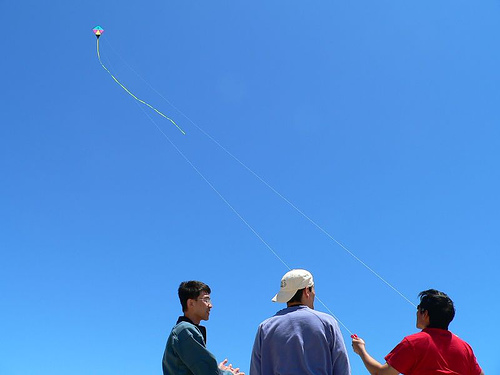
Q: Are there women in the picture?
A: No, there are no women.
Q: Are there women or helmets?
A: No, there are no women or helmets.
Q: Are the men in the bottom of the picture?
A: Yes, the men are in the bottom of the image.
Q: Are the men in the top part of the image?
A: No, the men are in the bottom of the image.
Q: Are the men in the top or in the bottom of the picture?
A: The men are in the bottom of the image.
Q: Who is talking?
A: The men are talking.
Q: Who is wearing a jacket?
A: The men are wearing a jacket.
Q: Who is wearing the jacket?
A: The men are wearing a jacket.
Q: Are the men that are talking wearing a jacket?
A: Yes, the men are wearing a jacket.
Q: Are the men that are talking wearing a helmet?
A: No, the men are wearing a jacket.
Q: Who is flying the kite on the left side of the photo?
A: The men are flying the kite.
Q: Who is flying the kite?
A: The men are flying the kite.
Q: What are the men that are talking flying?
A: The men are flying the kite.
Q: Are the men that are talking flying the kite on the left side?
A: Yes, the men are flying the kite.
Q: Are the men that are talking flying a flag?
A: No, the men are flying the kite.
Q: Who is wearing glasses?
A: The men are wearing glasses.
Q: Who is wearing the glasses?
A: The men are wearing glasses.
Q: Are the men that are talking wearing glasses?
A: Yes, the men are wearing glasses.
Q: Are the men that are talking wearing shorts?
A: No, the men are wearing glasses.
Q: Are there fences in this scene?
A: No, there are no fences.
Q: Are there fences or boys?
A: No, there are no fences or boys.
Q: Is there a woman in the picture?
A: No, there are no women.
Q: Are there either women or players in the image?
A: No, there are no women or players.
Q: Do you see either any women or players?
A: No, there are no women or players.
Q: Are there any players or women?
A: No, there are no women or players.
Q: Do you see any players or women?
A: No, there are no women or players.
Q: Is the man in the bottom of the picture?
A: Yes, the man is in the bottom of the image.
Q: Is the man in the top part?
A: No, the man is in the bottom of the image.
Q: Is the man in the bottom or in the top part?
A: The man is in the bottom of the image.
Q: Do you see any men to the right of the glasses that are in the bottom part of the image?
A: Yes, there is a man to the right of the glasses.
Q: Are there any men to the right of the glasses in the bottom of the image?
A: Yes, there is a man to the right of the glasses.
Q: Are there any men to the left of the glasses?
A: No, the man is to the right of the glasses.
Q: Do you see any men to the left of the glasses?
A: No, the man is to the right of the glasses.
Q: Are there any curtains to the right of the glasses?
A: No, there is a man to the right of the glasses.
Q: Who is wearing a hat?
A: The man is wearing a hat.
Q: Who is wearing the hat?
A: The man is wearing a hat.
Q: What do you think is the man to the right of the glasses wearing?
A: The man is wearing a hat.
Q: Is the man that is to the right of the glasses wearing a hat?
A: Yes, the man is wearing a hat.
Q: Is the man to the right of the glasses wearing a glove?
A: No, the man is wearing a hat.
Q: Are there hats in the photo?
A: Yes, there is a hat.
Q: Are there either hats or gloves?
A: Yes, there is a hat.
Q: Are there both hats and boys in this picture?
A: No, there is a hat but no boys.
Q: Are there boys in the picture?
A: No, there are no boys.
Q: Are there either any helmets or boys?
A: No, there are no boys or helmets.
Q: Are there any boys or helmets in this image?
A: No, there are no boys or helmets.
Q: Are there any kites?
A: Yes, there is a kite.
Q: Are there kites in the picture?
A: Yes, there is a kite.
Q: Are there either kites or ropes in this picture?
A: Yes, there is a kite.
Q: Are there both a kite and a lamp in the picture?
A: No, there is a kite but no lamps.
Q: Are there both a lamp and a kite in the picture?
A: No, there is a kite but no lamps.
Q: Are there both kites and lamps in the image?
A: No, there is a kite but no lamps.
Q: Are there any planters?
A: No, there are no planters.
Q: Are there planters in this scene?
A: No, there are no planters.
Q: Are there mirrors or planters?
A: No, there are no planters or mirrors.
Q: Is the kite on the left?
A: Yes, the kite is on the left of the image.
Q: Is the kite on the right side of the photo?
A: No, the kite is on the left of the image.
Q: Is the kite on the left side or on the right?
A: The kite is on the left of the image.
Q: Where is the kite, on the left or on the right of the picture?
A: The kite is on the left of the image.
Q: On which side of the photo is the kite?
A: The kite is on the left of the image.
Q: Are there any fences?
A: No, there are no fences.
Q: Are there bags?
A: No, there are no bags.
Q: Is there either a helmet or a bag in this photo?
A: No, there are no bags or helmets.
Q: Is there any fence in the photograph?
A: No, there are no fences.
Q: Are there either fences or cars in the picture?
A: No, there are no fences or cars.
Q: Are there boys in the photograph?
A: No, there are no boys.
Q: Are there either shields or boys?
A: No, there are no boys or shields.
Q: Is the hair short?
A: Yes, the hair is short.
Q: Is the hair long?
A: No, the hair is short.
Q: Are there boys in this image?
A: No, there are no boys.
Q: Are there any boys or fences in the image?
A: No, there are no boys or fences.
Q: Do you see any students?
A: No, there are no students.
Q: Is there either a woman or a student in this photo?
A: No, there are no students or women.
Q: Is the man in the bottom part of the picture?
A: Yes, the man is in the bottom of the image.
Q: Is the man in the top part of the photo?
A: No, the man is in the bottom of the image.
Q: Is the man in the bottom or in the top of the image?
A: The man is in the bottom of the image.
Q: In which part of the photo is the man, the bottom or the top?
A: The man is in the bottom of the image.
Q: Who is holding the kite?
A: The man is holding the kite.